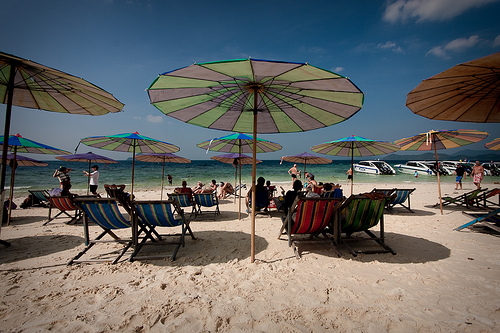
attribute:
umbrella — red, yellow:
[194, 126, 291, 163]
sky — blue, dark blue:
[1, 1, 488, 156]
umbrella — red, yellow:
[3, 50, 130, 124]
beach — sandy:
[284, 256, 421, 331]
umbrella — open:
[116, 21, 401, 174]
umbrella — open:
[1, 130, 78, 227]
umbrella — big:
[397, 120, 497, 175]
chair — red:
[292, 201, 337, 251]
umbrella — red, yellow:
[395, 126, 496, 159]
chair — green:
[341, 190, 396, 256]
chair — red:
[278, 194, 345, 256]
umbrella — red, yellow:
[3, 127, 74, 164]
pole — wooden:
[249, 72, 261, 264]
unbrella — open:
[146, 55, 365, 134]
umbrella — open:
[145, 52, 370, 137]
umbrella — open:
[311, 132, 400, 192]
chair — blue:
[127, 192, 203, 254]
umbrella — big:
[196, 131, 279, 215]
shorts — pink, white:
[470, 172, 485, 183]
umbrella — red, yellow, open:
[144, 50, 367, 265]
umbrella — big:
[307, 132, 402, 196]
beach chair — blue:
[65, 190, 133, 271]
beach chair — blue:
[124, 189, 201, 263]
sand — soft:
[9, 265, 495, 331]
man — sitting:
[247, 176, 271, 216]